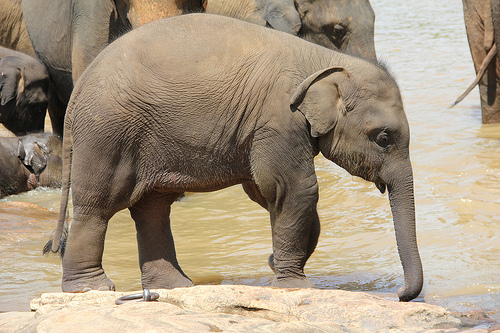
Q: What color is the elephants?
A: Gray.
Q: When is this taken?
A: During the day time.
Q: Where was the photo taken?
A: Wilderness.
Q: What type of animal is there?
A: Elephant.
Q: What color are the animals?
A: Gray.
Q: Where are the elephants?
A: Water.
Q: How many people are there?
A: None.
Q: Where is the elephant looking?
A: Down.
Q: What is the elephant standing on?
A: A rock.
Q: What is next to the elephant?
A: A rock.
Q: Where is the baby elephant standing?
A: In the river.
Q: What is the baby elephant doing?
A: Drinking water.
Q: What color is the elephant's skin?
A: Grey.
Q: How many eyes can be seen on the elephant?
A: One.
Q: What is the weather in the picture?
A: Sunny.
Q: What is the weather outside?
A: Sunny.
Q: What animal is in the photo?
A: An elephant.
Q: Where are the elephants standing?
A: In a river.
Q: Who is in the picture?
A: Elephants.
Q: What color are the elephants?
A: Grey.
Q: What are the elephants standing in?
A: Water.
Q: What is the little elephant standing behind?
A: A rock.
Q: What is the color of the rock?
A: Grey.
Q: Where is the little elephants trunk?
A: In the water.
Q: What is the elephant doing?
A: Drinking.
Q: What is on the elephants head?
A: Fuzzy hair.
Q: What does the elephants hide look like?
A: Wrinkled.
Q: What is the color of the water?
A: Brown.